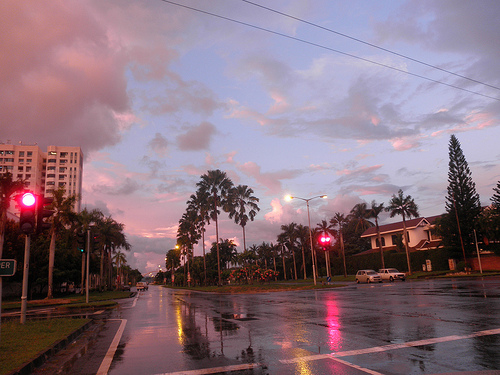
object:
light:
[20, 189, 37, 210]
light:
[321, 236, 329, 246]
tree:
[441, 135, 484, 271]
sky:
[0, 4, 500, 145]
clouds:
[304, 52, 407, 142]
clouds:
[390, 5, 496, 53]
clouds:
[145, 77, 221, 152]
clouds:
[116, 193, 183, 237]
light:
[287, 193, 330, 285]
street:
[27, 282, 499, 375]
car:
[378, 265, 405, 284]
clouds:
[420, 81, 500, 135]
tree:
[384, 189, 422, 276]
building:
[39, 146, 81, 224]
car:
[354, 267, 385, 284]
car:
[136, 278, 148, 292]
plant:
[229, 265, 244, 286]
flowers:
[267, 269, 276, 277]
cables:
[239, 0, 500, 92]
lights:
[157, 263, 163, 286]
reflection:
[325, 285, 344, 374]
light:
[173, 243, 182, 251]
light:
[167, 252, 179, 284]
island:
[162, 245, 328, 296]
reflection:
[173, 295, 186, 348]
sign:
[0, 260, 17, 277]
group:
[193, 171, 236, 286]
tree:
[221, 182, 259, 286]